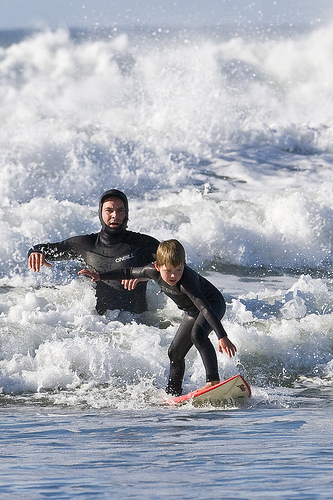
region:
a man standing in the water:
[11, 130, 330, 459]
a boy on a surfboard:
[119, 234, 268, 472]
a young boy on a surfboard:
[105, 220, 304, 431]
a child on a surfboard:
[124, 238, 292, 424]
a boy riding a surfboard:
[126, 230, 305, 436]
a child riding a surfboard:
[126, 221, 273, 436]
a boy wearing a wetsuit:
[113, 236, 304, 464]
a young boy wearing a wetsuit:
[126, 230, 260, 450]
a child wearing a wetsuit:
[102, 236, 302, 440]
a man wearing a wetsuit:
[39, 184, 197, 387]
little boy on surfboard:
[80, 249, 239, 392]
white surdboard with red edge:
[184, 370, 259, 406]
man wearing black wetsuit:
[40, 184, 165, 305]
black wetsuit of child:
[99, 257, 237, 384]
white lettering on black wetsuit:
[112, 253, 135, 267]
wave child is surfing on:
[18, 285, 315, 393]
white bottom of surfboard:
[199, 377, 250, 406]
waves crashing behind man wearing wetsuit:
[15, 33, 320, 241]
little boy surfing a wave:
[76, 243, 262, 409]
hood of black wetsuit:
[93, 183, 131, 230]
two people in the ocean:
[28, 190, 262, 419]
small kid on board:
[112, 240, 249, 431]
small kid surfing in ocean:
[83, 225, 260, 420]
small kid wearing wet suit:
[81, 232, 237, 369]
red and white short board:
[150, 375, 250, 422]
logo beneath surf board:
[236, 381, 249, 395]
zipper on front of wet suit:
[149, 278, 178, 307]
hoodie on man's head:
[92, 179, 126, 241]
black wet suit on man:
[31, 222, 178, 319]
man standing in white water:
[21, 188, 172, 326]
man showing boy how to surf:
[24, 181, 287, 433]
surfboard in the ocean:
[159, 369, 264, 414]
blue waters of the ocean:
[26, 432, 321, 488]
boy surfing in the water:
[73, 238, 267, 393]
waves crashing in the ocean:
[188, 148, 310, 267]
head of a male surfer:
[88, 180, 137, 241]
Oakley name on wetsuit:
[111, 248, 138, 264]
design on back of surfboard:
[231, 381, 249, 395]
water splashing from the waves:
[131, 19, 208, 40]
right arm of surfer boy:
[76, 256, 146, 288]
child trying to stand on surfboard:
[81, 240, 233, 386]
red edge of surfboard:
[174, 371, 252, 404]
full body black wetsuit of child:
[100, 263, 227, 397]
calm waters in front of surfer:
[9, 407, 313, 499]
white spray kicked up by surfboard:
[78, 376, 288, 414]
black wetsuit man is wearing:
[44, 235, 161, 305]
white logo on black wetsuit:
[110, 250, 135, 266]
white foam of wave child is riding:
[8, 281, 328, 383]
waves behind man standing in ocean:
[6, 41, 320, 248]